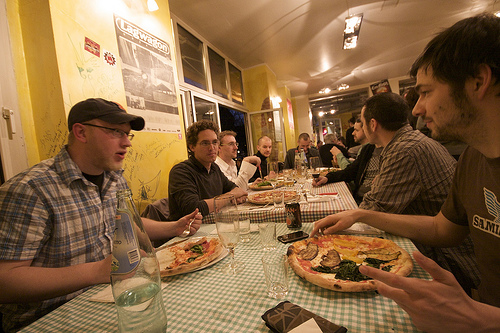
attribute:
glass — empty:
[258, 246, 295, 298]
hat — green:
[53, 89, 164, 150]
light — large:
[336, 12, 364, 60]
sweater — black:
[167, 154, 237, 220]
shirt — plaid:
[5, 140, 149, 310]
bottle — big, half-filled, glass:
[107, 185, 177, 330]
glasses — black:
[224, 140, 242, 147]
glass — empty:
[263, 251, 286, 299]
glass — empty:
[257, 220, 277, 252]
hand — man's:
[172, 205, 205, 240]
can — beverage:
[282, 200, 304, 232]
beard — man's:
[446, 83, 483, 140]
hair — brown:
[183, 121, 219, 146]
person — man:
[7, 96, 166, 273]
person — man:
[177, 123, 234, 205]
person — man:
[401, 13, 491, 277]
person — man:
[347, 86, 438, 206]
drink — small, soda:
[283, 197, 306, 231]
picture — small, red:
[103, 46, 119, 68]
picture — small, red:
[78, 30, 102, 58]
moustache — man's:
[424, 112, 441, 131]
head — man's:
[62, 101, 135, 174]